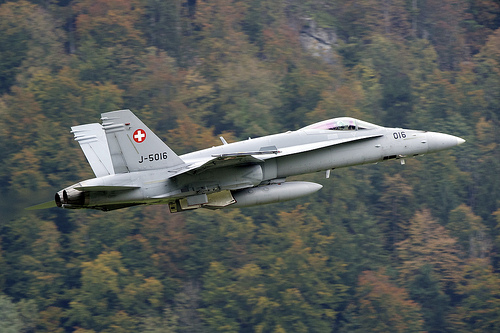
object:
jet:
[21, 103, 469, 217]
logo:
[131, 126, 148, 143]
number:
[135, 151, 176, 163]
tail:
[94, 103, 187, 172]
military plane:
[51, 107, 466, 208]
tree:
[113, 228, 424, 332]